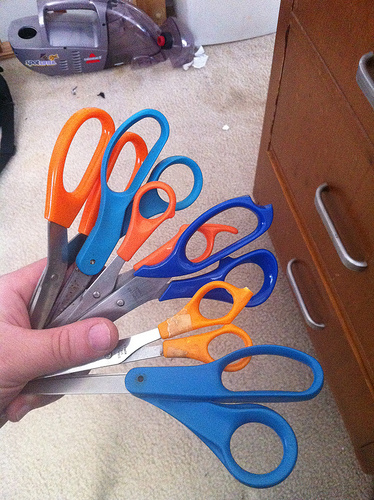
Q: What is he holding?
A: Scissors.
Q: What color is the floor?
A: Gray.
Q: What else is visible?
A: Drawer.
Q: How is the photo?
A: Clear.